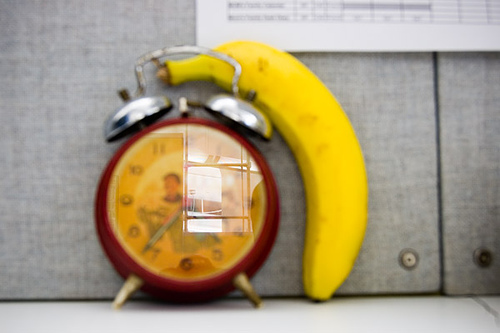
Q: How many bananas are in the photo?
A: One.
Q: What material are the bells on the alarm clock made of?
A: Metal.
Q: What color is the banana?
A: Yellow.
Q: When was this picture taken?
A: 4:37.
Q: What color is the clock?
A: Red.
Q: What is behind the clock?
A: A cubicle.